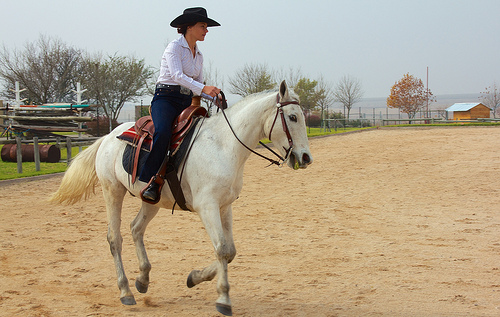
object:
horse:
[47, 79, 313, 316]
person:
[140, 7, 227, 205]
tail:
[47, 137, 103, 207]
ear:
[279, 80, 289, 99]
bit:
[278, 147, 294, 168]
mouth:
[288, 151, 306, 169]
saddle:
[114, 95, 209, 212]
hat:
[169, 7, 220, 28]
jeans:
[138, 83, 194, 182]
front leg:
[191, 198, 232, 316]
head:
[170, 7, 222, 41]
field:
[0, 123, 499, 316]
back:
[93, 121, 137, 174]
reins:
[216, 94, 280, 165]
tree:
[386, 72, 437, 124]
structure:
[445, 102, 494, 123]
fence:
[1, 135, 101, 174]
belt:
[156, 84, 181, 90]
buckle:
[179, 86, 190, 96]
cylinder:
[1, 144, 61, 163]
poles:
[1, 114, 94, 122]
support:
[9, 81, 29, 105]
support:
[71, 82, 88, 152]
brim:
[170, 14, 222, 27]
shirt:
[155, 34, 204, 96]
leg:
[101, 182, 139, 305]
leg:
[130, 202, 161, 294]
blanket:
[116, 115, 203, 156]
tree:
[332, 74, 366, 125]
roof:
[444, 102, 493, 112]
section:
[16, 138, 72, 172]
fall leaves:
[386, 72, 437, 114]